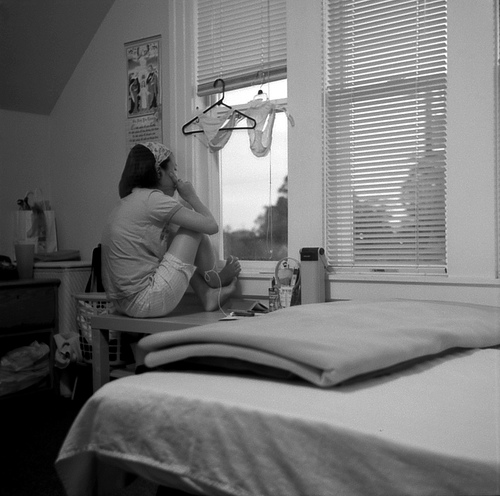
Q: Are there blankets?
A: Yes, there is a blanket.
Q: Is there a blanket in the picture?
A: Yes, there is a blanket.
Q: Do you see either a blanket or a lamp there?
A: Yes, there is a blanket.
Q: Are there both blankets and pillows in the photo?
A: No, there is a blanket but no pillows.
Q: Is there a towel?
A: No, there are no towels.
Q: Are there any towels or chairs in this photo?
A: No, there are no towels or chairs.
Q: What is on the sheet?
A: The blanket is on the sheet.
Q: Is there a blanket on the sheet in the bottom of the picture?
A: Yes, there is a blanket on the bed sheet.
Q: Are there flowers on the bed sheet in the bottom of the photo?
A: No, there is a blanket on the sheet.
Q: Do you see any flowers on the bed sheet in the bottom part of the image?
A: No, there is a blanket on the sheet.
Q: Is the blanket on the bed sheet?
A: Yes, the blanket is on the bed sheet.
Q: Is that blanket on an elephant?
A: No, the blanket is on the bed sheet.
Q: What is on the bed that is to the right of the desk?
A: The blanket is on the bed.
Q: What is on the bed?
A: The blanket is on the bed.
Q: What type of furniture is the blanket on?
A: The blanket is on the bed.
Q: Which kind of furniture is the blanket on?
A: The blanket is on the bed.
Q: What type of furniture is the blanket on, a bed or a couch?
A: The blanket is on a bed.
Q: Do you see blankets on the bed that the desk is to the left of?
A: Yes, there is a blanket on the bed.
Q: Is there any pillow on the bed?
A: No, there is a blanket on the bed.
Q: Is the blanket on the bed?
A: Yes, the blanket is on the bed.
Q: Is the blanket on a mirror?
A: No, the blanket is on the bed.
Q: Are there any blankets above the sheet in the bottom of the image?
A: Yes, there is a blanket above the sheet.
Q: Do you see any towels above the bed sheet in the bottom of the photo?
A: No, there is a blanket above the bed sheet.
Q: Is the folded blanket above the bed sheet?
A: Yes, the blanket is above the bed sheet.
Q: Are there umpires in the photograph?
A: No, there are no umpires.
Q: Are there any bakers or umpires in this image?
A: No, there are no umpires or bakers.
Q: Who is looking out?
A: The girl is looking out.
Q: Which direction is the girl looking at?
A: The girl is looking out.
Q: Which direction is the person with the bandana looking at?
A: The girl is looking out.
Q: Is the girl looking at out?
A: Yes, the girl is looking out.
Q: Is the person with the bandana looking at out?
A: Yes, the girl is looking out.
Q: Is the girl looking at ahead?
A: No, the girl is looking out.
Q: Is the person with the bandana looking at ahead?
A: No, the girl is looking out.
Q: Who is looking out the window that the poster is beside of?
A: The girl is looking out the window.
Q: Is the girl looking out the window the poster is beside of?
A: Yes, the girl is looking out the window.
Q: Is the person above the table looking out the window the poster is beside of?
A: Yes, the girl is looking out the window.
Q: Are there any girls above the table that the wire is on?
A: Yes, there is a girl above the table.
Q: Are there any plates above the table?
A: No, there is a girl above the table.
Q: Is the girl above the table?
A: Yes, the girl is above the table.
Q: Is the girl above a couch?
A: No, the girl is above the table.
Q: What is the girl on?
A: The girl is on the table.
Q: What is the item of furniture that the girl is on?
A: The piece of furniture is a table.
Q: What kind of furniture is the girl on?
A: The girl is on the table.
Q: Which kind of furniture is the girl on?
A: The girl is on the table.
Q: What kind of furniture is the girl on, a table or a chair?
A: The girl is on a table.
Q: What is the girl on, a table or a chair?
A: The girl is on a table.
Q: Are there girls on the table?
A: Yes, there is a girl on the table.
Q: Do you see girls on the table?
A: Yes, there is a girl on the table.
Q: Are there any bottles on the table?
A: No, there is a girl on the table.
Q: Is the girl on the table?
A: Yes, the girl is on the table.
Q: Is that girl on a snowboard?
A: No, the girl is on the table.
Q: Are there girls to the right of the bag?
A: Yes, there is a girl to the right of the bag.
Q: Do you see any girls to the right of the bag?
A: Yes, there is a girl to the right of the bag.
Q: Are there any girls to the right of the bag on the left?
A: Yes, there is a girl to the right of the bag.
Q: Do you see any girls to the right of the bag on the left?
A: Yes, there is a girl to the right of the bag.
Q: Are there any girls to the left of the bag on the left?
A: No, the girl is to the right of the bag.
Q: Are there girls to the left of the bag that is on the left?
A: No, the girl is to the right of the bag.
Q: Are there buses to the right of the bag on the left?
A: No, there is a girl to the right of the bag.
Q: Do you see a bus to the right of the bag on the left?
A: No, there is a girl to the right of the bag.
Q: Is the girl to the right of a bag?
A: Yes, the girl is to the right of a bag.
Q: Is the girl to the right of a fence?
A: No, the girl is to the right of a bag.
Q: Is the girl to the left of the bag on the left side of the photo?
A: No, the girl is to the right of the bag.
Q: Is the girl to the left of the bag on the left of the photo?
A: No, the girl is to the right of the bag.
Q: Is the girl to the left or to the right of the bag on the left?
A: The girl is to the right of the bag.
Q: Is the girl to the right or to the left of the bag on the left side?
A: The girl is to the right of the bag.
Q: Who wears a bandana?
A: The girl wears a bandana.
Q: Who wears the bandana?
A: The girl wears a bandana.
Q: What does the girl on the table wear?
A: The girl wears a bandana.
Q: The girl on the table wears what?
A: The girl wears a bandana.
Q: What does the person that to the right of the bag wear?
A: The girl wears a bandana.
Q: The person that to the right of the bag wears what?
A: The girl wears a bandana.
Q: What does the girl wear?
A: The girl wears a bandana.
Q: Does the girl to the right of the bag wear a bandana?
A: Yes, the girl wears a bandana.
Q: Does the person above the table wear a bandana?
A: Yes, the girl wears a bandana.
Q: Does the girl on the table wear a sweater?
A: No, the girl wears a bandana.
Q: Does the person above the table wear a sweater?
A: No, the girl wears a bandana.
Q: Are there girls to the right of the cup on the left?
A: Yes, there is a girl to the right of the cup.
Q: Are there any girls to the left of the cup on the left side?
A: No, the girl is to the right of the cup.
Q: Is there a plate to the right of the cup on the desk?
A: No, there is a girl to the right of the cup.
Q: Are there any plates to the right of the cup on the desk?
A: No, there is a girl to the right of the cup.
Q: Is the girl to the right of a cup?
A: Yes, the girl is to the right of a cup.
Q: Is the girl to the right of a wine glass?
A: No, the girl is to the right of a cup.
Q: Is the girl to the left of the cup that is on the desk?
A: No, the girl is to the right of the cup.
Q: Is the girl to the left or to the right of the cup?
A: The girl is to the right of the cup.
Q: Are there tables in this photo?
A: Yes, there is a table.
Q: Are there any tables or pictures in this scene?
A: Yes, there is a table.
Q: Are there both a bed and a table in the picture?
A: Yes, there are both a table and a bed.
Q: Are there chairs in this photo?
A: No, there are no chairs.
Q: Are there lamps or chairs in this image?
A: No, there are no chairs or lamps.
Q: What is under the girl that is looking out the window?
A: The table is under the girl.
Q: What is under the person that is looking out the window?
A: The table is under the girl.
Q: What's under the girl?
A: The table is under the girl.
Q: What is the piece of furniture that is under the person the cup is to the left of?
A: The piece of furniture is a table.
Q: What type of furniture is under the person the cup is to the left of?
A: The piece of furniture is a table.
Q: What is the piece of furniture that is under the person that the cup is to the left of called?
A: The piece of furniture is a table.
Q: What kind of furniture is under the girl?
A: The piece of furniture is a table.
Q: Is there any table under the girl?
A: Yes, there is a table under the girl.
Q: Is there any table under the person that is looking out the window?
A: Yes, there is a table under the girl.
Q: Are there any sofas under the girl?
A: No, there is a table under the girl.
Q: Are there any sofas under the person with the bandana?
A: No, there is a table under the girl.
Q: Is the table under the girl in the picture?
A: Yes, the table is under the girl.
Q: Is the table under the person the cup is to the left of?
A: Yes, the table is under the girl.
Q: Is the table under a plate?
A: No, the table is under the girl.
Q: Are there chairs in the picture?
A: No, there are no chairs.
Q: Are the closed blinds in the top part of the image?
A: Yes, the blinds are in the top of the image.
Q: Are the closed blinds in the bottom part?
A: No, the blinds are in the top of the image.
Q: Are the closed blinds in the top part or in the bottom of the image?
A: The blinds are in the top of the image.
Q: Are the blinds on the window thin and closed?
A: Yes, the blinds are thin and closed.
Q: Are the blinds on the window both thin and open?
A: No, the blinds are thin but closed.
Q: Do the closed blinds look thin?
A: Yes, the blinds are thin.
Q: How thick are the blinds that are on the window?
A: The blinds are thin.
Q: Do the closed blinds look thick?
A: No, the blinds are thin.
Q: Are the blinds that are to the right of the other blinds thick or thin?
A: The blinds are thin.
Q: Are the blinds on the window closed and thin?
A: Yes, the blinds are closed and thin.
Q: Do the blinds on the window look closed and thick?
A: No, the blinds are closed but thin.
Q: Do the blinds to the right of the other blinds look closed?
A: Yes, the blinds are closed.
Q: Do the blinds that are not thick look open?
A: No, the blinds are closed.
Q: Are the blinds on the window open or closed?
A: The blinds are closed.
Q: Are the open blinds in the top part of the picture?
A: Yes, the blinds are in the top of the image.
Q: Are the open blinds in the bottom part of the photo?
A: No, the blinds are in the top of the image.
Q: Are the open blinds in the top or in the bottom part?
A: The blinds are in the top of the image.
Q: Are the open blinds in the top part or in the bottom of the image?
A: The blinds are in the top of the image.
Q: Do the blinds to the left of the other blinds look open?
A: Yes, the blinds are open.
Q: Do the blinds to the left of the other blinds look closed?
A: No, the blinds are open.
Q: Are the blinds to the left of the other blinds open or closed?
A: The blinds are open.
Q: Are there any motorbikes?
A: No, there are no motorbikes.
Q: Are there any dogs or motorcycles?
A: No, there are no motorcycles or dogs.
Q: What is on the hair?
A: The bandana is on the hair.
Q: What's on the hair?
A: The bandana is on the hair.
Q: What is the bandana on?
A: The bandana is on the hair.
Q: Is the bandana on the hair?
A: Yes, the bandana is on the hair.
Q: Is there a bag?
A: Yes, there is a bag.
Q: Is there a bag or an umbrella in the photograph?
A: Yes, there is a bag.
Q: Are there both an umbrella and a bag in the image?
A: No, there is a bag but no umbrellas.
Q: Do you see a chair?
A: No, there are no chairs.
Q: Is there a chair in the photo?
A: No, there are no chairs.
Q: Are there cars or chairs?
A: No, there are no chairs or cars.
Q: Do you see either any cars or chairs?
A: No, there are no chairs or cars.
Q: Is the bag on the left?
A: Yes, the bag is on the left of the image.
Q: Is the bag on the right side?
A: No, the bag is on the left of the image.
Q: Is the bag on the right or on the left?
A: The bag is on the left of the image.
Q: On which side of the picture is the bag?
A: The bag is on the left of the image.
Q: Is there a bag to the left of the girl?
A: Yes, there is a bag to the left of the girl.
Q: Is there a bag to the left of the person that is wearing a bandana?
A: Yes, there is a bag to the left of the girl.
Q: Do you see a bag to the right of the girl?
A: No, the bag is to the left of the girl.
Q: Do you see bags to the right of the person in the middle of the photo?
A: No, the bag is to the left of the girl.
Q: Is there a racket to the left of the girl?
A: No, there is a bag to the left of the girl.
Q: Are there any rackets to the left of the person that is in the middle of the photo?
A: No, there is a bag to the left of the girl.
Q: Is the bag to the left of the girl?
A: Yes, the bag is to the left of the girl.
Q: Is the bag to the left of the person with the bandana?
A: Yes, the bag is to the left of the girl.